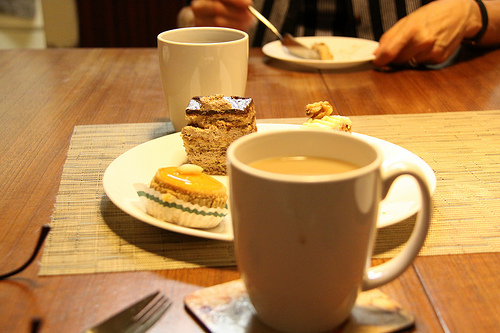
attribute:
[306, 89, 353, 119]
nut — big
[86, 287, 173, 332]
fork — BIG, SILVER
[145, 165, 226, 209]
brown dessert — light brown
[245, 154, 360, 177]
coffee — a lot, light brown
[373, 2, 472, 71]
hand — big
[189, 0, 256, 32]
hand — big